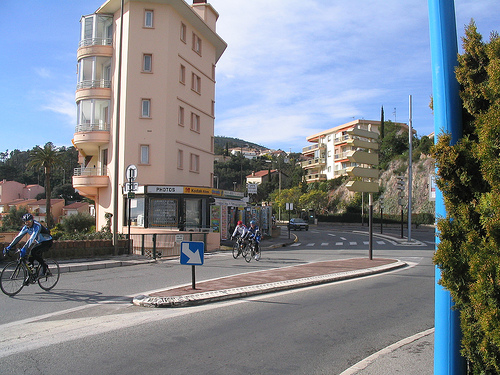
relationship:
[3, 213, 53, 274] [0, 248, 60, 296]
man riding bicycle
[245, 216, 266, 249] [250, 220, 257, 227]
man wears helmet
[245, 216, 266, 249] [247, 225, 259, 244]
man wears clothes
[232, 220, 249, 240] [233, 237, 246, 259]
person riding bicycle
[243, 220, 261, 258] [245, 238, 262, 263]
man riding bicycle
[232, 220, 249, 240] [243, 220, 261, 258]
person by man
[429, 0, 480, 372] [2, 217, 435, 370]
pole on street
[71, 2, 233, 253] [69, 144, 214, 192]
building has floor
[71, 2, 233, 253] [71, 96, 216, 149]
building has floor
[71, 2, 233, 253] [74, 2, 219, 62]
building has floor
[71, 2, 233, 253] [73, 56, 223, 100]
building has floor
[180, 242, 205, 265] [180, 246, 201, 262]
sign has background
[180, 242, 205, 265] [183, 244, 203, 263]
sign has arrow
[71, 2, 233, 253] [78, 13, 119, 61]
building has balcony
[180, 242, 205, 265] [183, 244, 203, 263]
sign with arrow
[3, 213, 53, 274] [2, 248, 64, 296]
man on bicycle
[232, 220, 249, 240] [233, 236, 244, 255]
person on bicycle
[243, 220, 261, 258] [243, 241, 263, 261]
man on bicycle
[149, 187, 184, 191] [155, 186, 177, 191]
sign with lettering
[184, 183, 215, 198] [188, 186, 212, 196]
sign with lettering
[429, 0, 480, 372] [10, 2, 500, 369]
pole in photograph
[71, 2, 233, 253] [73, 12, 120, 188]
building with stories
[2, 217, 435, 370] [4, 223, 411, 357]
street with paint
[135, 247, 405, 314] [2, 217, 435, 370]
sidewalk dividing street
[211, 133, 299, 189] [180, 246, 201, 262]
mountain in background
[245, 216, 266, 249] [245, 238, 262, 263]
man on bicycle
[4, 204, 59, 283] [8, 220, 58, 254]
man with shirt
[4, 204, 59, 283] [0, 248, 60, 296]
man on bicycle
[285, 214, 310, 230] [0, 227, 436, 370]
car on street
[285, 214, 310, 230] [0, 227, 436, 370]
car driving on street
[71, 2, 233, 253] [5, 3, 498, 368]
building in city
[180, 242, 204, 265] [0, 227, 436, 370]
sign on street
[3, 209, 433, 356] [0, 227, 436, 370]
lines on street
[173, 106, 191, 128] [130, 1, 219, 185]
window attached to wall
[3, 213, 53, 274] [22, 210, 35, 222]
man wearing helmet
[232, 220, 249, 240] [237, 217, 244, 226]
person wearing helmet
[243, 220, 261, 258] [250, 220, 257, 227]
man wearing helmet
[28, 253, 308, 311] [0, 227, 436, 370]
shadow on street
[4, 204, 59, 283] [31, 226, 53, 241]
man wearing black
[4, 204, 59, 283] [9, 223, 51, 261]
man wearing blue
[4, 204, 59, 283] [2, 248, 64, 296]
man on bicycle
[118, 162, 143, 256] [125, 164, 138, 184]
post with sign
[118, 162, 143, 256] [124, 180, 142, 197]
post with sign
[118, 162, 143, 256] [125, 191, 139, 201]
post with sign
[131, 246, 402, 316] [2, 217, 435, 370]
median in street